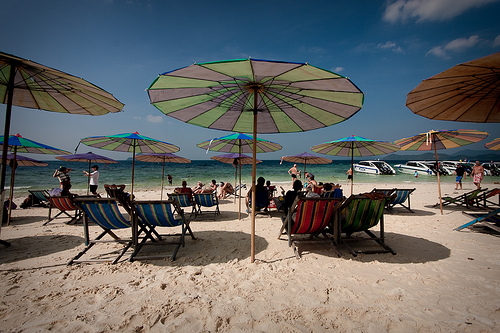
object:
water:
[0, 133, 500, 189]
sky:
[1, 1, 500, 156]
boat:
[350, 156, 399, 178]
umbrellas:
[0, 49, 500, 235]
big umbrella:
[139, 54, 399, 264]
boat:
[391, 156, 448, 176]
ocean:
[0, 152, 500, 185]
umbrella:
[0, 50, 130, 222]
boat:
[392, 163, 440, 178]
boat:
[437, 157, 470, 178]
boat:
[444, 160, 495, 176]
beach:
[0, 256, 499, 331]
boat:
[440, 158, 493, 178]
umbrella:
[399, 50, 498, 129]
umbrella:
[397, 120, 497, 217]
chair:
[381, 187, 420, 216]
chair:
[190, 192, 225, 222]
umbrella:
[1, 155, 52, 231]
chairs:
[56, 193, 200, 271]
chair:
[334, 190, 395, 256]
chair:
[278, 194, 344, 263]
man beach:
[238, 176, 285, 225]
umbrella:
[135, 47, 473, 265]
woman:
[78, 160, 102, 198]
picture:
[1, 1, 496, 333]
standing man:
[345, 167, 356, 188]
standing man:
[284, 162, 302, 185]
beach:
[0, 144, 497, 331]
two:
[51, 157, 106, 197]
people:
[50, 156, 104, 202]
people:
[235, 172, 346, 215]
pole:
[245, 72, 262, 268]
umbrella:
[145, 52, 369, 267]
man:
[468, 160, 487, 193]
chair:
[127, 192, 191, 266]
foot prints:
[116, 266, 222, 311]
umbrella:
[196, 131, 284, 219]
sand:
[152, 187, 321, 333]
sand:
[367, 177, 500, 333]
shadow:
[128, 226, 271, 269]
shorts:
[470, 172, 485, 184]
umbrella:
[0, 129, 74, 231]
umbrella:
[57, 150, 118, 199]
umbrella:
[76, 128, 184, 213]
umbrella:
[131, 148, 191, 203]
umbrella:
[211, 152, 266, 205]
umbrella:
[191, 132, 288, 210]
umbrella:
[278, 147, 335, 187]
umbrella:
[307, 132, 402, 196]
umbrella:
[389, 122, 490, 218]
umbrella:
[401, 45, 499, 127]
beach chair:
[65, 190, 133, 271]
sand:
[0, 265, 495, 332]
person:
[52, 162, 73, 197]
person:
[82, 163, 101, 199]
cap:
[90, 164, 100, 168]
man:
[242, 176, 274, 219]